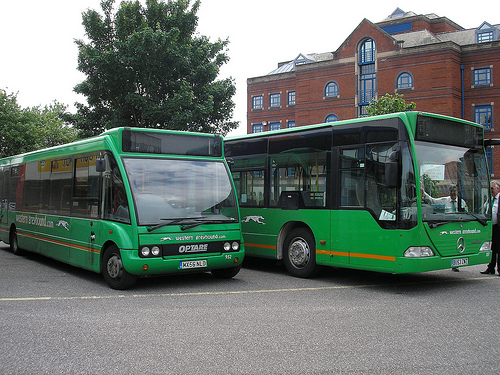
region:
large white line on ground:
[13, 284, 156, 321]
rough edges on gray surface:
[104, 291, 321, 360]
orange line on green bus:
[298, 239, 409, 266]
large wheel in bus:
[268, 217, 335, 276]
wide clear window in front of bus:
[105, 142, 253, 242]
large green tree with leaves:
[78, 22, 228, 92]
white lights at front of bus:
[136, 230, 253, 260]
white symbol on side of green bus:
[13, 202, 88, 236]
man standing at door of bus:
[412, 165, 474, 228]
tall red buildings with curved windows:
[287, 37, 478, 98]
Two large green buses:
[2, 107, 495, 284]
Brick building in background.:
[241, 4, 499, 137]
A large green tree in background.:
[71, 0, 227, 133]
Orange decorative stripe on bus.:
[241, 236, 399, 268]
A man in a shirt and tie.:
[487, 174, 499, 271]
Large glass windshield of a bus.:
[121, 151, 245, 230]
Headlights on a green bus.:
[137, 236, 242, 259]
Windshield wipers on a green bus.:
[143, 217, 240, 236]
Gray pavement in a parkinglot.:
[0, 281, 497, 365]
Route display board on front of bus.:
[114, 123, 227, 165]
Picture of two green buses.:
[23, 32, 499, 336]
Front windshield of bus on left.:
[123, 157, 242, 237]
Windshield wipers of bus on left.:
[141, 205, 246, 237]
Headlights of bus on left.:
[127, 237, 251, 261]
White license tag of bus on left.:
[175, 253, 218, 276]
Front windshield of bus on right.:
[408, 129, 498, 225]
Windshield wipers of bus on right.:
[424, 212, 489, 232]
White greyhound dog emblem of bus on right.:
[240, 210, 270, 227]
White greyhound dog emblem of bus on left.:
[56, 215, 71, 230]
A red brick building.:
[248, 10, 490, 120]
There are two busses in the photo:
[8, 76, 493, 280]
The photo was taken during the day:
[3, 81, 496, 344]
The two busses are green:
[32, 101, 474, 371]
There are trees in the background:
[11, 13, 474, 360]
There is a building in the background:
[98, 28, 498, 337]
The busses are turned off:
[50, 87, 492, 347]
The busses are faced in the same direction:
[45, 109, 496, 310]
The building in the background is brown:
[170, 18, 475, 329]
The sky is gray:
[8, 14, 424, 189]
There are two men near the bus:
[366, 113, 496, 235]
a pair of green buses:
[1, 110, 492, 290]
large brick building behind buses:
[246, 7, 498, 182]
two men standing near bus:
[423, 173, 496, 279]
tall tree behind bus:
[60, 0, 241, 140]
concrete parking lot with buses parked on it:
[0, 233, 498, 373]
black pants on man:
[487, 229, 498, 268]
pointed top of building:
[333, 16, 403, 56]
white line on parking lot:
[2, 279, 465, 303]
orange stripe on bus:
[0, 219, 101, 261]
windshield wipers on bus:
[146, 211, 238, 247]